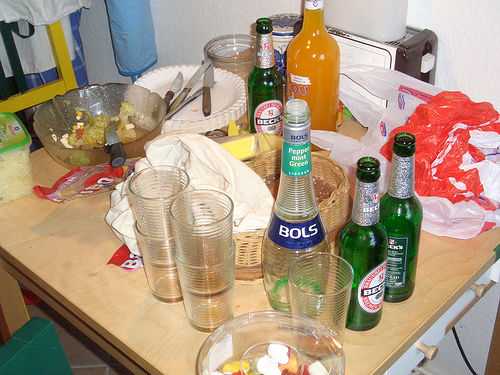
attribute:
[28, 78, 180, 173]
bowl — glass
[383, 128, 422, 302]
bottle — empty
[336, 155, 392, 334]
bottle — empty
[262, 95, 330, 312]
bottle — empty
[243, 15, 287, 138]
bottle — empty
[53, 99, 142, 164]
food — leftover party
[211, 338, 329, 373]
food — leftover party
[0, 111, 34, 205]
food — leftover party